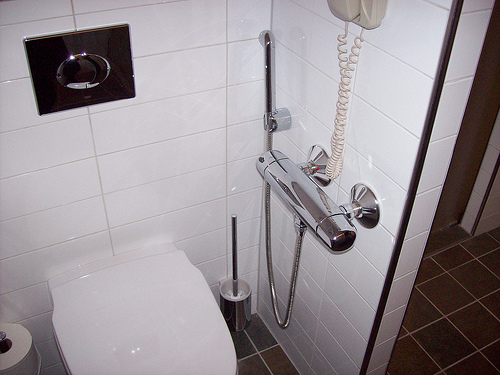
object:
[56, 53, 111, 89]
button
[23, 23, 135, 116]
plate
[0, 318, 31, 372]
tissue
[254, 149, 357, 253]
handlebar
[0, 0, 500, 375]
wall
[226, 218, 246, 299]
toilet brush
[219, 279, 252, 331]
canister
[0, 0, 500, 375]
white tiles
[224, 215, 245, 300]
scrub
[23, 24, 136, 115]
silver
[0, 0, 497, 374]
tiled wall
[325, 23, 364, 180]
cord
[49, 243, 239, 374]
toilet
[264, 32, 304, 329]
pipe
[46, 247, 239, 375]
tank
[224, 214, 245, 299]
brush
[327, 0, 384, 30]
phone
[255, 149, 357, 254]
dryer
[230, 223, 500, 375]
tile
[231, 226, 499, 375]
floor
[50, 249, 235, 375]
bowl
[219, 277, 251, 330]
cup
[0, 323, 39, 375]
roll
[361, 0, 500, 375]
door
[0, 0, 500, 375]
bathroom